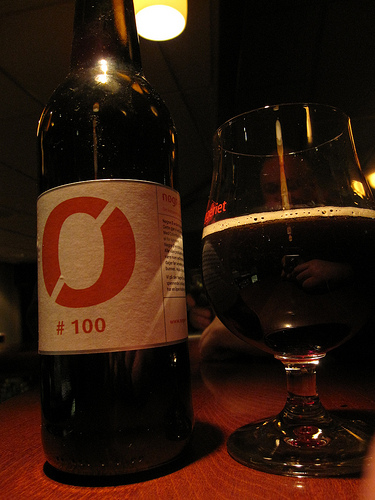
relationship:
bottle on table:
[34, 0, 192, 473] [6, 326, 372, 497]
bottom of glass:
[229, 331, 373, 354] [199, 96, 372, 482]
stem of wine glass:
[270, 355, 342, 423] [199, 100, 373, 477]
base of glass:
[221, 397, 362, 474] [220, 109, 333, 279]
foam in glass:
[202, 208, 371, 235] [199, 96, 372, 482]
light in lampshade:
[130, 1, 213, 56] [115, 0, 196, 38]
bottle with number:
[2, 10, 208, 498] [36, 183, 168, 356]